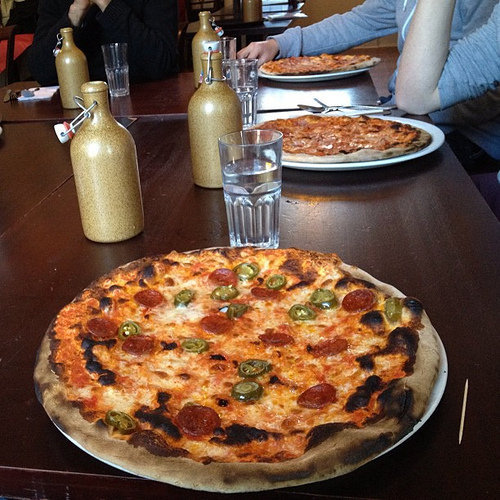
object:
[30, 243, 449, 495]
dish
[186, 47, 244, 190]
bottle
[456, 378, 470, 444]
toothpick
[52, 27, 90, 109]
bottle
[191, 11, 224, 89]
bottle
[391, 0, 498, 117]
arm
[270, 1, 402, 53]
arm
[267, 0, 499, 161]
jumper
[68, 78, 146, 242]
bottle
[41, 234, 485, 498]
pasta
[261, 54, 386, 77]
pizza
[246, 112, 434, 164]
pizza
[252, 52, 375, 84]
plate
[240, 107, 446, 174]
plate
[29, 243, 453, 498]
plate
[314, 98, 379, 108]
fork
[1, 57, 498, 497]
table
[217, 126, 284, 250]
glass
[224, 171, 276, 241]
water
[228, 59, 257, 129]
glass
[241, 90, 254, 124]
water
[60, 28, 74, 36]
brim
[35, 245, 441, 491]
pie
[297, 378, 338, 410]
pepperoni